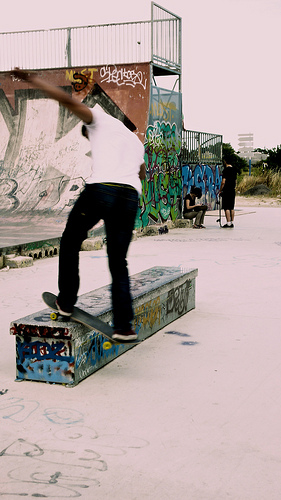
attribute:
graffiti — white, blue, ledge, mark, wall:
[0, 176, 54, 231]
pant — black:
[50, 194, 142, 301]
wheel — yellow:
[96, 334, 122, 360]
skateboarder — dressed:
[43, 71, 236, 284]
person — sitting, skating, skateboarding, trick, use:
[177, 177, 220, 236]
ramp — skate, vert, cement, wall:
[144, 242, 221, 329]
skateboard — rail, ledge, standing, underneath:
[32, 274, 189, 412]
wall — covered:
[132, 167, 191, 197]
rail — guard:
[160, 260, 188, 296]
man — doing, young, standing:
[19, 53, 191, 362]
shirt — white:
[92, 139, 151, 176]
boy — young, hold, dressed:
[81, 74, 168, 177]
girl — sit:
[187, 181, 213, 220]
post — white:
[141, 24, 189, 86]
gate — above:
[127, 31, 186, 110]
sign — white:
[239, 126, 264, 149]